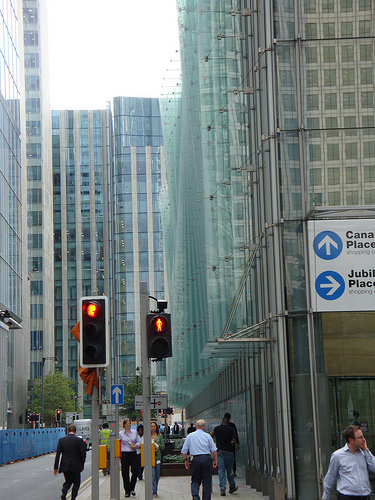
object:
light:
[80, 294, 111, 368]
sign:
[299, 213, 373, 317]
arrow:
[314, 272, 343, 299]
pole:
[75, 294, 112, 498]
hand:
[361, 437, 368, 451]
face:
[350, 430, 364, 449]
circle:
[310, 229, 347, 259]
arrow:
[316, 233, 337, 255]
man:
[181, 416, 220, 498]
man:
[50, 420, 89, 498]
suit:
[56, 432, 85, 490]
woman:
[117, 413, 141, 498]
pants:
[119, 448, 141, 491]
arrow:
[111, 385, 121, 402]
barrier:
[0, 428, 56, 466]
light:
[153, 317, 165, 332]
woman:
[150, 419, 168, 495]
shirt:
[152, 432, 166, 459]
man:
[320, 418, 375, 497]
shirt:
[324, 445, 374, 493]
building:
[55, 102, 113, 418]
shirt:
[180, 426, 219, 457]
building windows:
[303, 64, 357, 113]